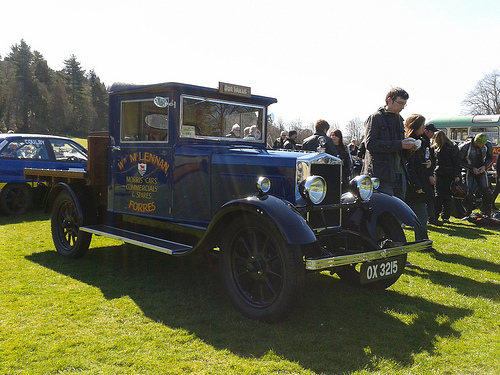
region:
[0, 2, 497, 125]
light in daytime sky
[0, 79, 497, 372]
antique truck parked on green grass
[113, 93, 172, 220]
words on truck door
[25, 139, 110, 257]
bed of truck over wheel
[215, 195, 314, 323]
shiny fender over wheel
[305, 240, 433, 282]
license plate under bumper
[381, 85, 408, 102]
man with black hair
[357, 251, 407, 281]
license plate on the car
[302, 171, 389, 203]
head lights on the car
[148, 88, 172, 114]
mirror on the car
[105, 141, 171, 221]
Sign on the car door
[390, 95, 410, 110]
man wearing reading glasses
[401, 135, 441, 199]
woman wearing a black jacket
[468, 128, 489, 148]
man wearing a green hat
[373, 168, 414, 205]
man wearing blue jeans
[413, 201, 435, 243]
woman wearing blue jeans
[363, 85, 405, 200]
A man walks with a jacket.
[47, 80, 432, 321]
An antique blue car.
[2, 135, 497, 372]
The grass is cut short.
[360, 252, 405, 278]
6 letter word license plate.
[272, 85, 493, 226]
A crowd of people stands outside.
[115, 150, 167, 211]
Yellow text on the car.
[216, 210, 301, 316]
A car has dark rims.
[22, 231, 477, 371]
The vehicle makes a large shadow.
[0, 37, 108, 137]
Oak trees in the back.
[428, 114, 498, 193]
Bus with a light blue color.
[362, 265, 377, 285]
this is a number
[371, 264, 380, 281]
this is a number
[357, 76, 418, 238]
this is a person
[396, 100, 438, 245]
this is a person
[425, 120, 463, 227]
this is a person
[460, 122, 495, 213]
this is a person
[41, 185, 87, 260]
this is a tyre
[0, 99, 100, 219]
this is a vehicle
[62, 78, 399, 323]
old blue truck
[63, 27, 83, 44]
white clouds in blue sky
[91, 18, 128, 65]
white clouds in blue sky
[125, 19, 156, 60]
white clouds in blue sky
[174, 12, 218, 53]
white clouds in blue sky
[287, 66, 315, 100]
white clouds in blue sky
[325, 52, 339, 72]
white clouds in blue sky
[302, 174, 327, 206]
a vintage car headlight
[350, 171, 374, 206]
a vintage car headlight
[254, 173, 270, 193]
a vintage car turn signal